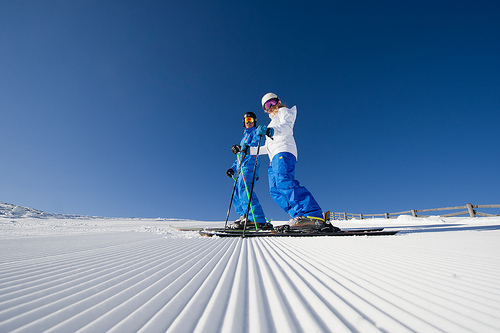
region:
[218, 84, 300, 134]
faces of the person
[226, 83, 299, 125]
faces of the man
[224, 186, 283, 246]
shoe of the man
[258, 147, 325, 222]
a man wearing pants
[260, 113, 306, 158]
a man wearing shirt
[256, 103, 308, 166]
a man wearing jacket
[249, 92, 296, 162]
a man wearing white jacket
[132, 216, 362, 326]
a snow in the ground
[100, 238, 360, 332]
a lines in the snow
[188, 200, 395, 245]
a skatting macine in ice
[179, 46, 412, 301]
two people skiing on a clear day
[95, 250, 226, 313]
perfectly groomed snow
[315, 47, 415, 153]
a clear blue sky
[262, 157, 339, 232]
a pair of blue snow pants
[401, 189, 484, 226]
a wooden fence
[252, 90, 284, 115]
a woman wearing goggles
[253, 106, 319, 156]
a woman in a white jacket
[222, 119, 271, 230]
a man wearing a blue snow suit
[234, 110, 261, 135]
a black ski helmet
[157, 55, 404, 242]
Two people on a mountain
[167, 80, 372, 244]
The people are on skis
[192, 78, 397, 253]
The people are looking at the camera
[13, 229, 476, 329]
The ground is covered in snow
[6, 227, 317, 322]
There are many lines on the ground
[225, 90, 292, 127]
They are both wearing helmets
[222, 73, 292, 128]
They are both wearing ski goggles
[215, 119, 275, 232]
They are both holding ski poles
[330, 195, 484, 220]
A wooden fence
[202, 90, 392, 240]
The women are stationary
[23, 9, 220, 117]
Dark blue skies above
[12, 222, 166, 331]
Large body of white snow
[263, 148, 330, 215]
The person has blue pants on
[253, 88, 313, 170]
The person has a smile on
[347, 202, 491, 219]
Fence in the background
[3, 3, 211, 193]
Large body of dark blue skies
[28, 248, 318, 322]
Lines in the white snow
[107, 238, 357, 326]
trails in the snow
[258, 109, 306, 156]
man wearing a white jacket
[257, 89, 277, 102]
man wearing a white helmet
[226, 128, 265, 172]
man wearing a blue jacket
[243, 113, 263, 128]
man wearing dark shades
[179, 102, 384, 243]
Man and woman on skis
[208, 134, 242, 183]
man wearing black gloves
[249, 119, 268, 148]
woman wearing blue gloves